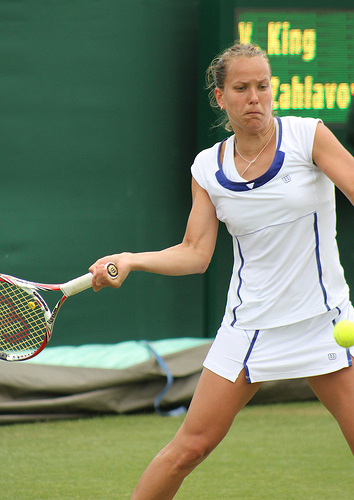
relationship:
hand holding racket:
[88, 252, 133, 291] [1, 258, 119, 365]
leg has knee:
[131, 364, 262, 499] [163, 437, 213, 471]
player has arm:
[87, 44, 351, 499] [122, 161, 218, 277]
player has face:
[87, 44, 351, 499] [223, 55, 271, 131]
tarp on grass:
[1, 338, 317, 423] [1, 400, 352, 499]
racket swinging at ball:
[1, 258, 119, 365] [331, 318, 353, 348]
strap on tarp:
[134, 339, 186, 419] [1, 338, 317, 423]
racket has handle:
[1, 258, 119, 365] [58, 262, 121, 300]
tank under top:
[222, 133, 251, 184] [191, 116, 351, 334]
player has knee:
[87, 44, 351, 499] [163, 437, 213, 471]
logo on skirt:
[327, 349, 339, 361] [200, 296, 349, 384]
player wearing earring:
[87, 44, 351, 499] [218, 102, 226, 111]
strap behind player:
[134, 339, 186, 419] [87, 44, 351, 499]